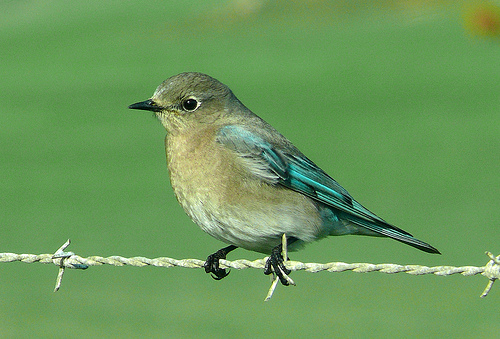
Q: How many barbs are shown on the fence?
A: Three.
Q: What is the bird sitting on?
A: Barbed wire fence.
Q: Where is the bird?
A: On a fence.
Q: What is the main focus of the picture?
A: A bird.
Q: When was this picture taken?
A: Daytime.